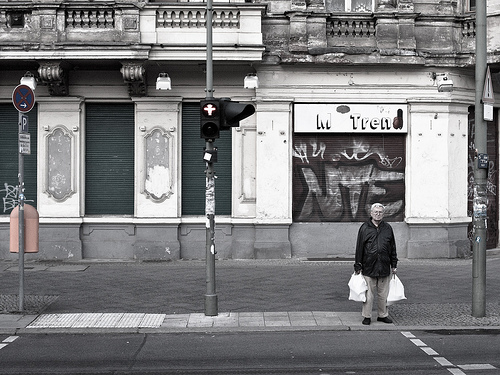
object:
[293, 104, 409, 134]
sign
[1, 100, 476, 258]
shop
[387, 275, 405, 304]
food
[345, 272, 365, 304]
food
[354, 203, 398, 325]
gentleman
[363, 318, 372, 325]
shoes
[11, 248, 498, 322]
sidewalk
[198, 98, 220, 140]
light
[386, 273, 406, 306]
bag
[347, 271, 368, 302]
bag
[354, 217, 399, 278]
coat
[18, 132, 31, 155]
sign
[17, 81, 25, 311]
metallic pole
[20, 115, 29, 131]
sign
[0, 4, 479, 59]
railings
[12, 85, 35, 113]
sign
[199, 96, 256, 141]
fixture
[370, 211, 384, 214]
glasses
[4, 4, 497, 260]
city